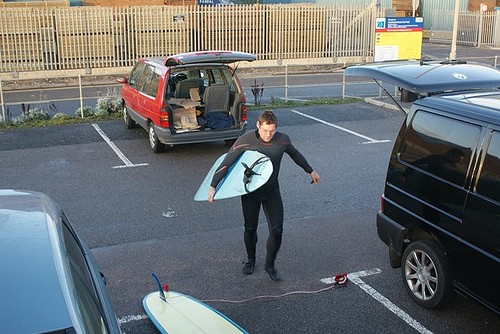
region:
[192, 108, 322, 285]
man walking with surfboard in arm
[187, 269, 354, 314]
red ankle band of surfboard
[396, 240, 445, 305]
silver rims on black van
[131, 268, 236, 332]
blue and white surfboard on pavement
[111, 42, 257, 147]
red van with hatch open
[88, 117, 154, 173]
white line on parking lot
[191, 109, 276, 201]
Surfboard under man's arm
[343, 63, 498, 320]
Black van with trunk open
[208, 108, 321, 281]
Man in black wetsuit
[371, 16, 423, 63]
Yellow, blue, red, and white sign on fence.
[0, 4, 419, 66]
White fence in front of brown pallets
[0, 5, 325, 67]
Five large brown boxes behind fence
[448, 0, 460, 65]
White pole in front of fence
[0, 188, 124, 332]
Blue car parked in parking lot.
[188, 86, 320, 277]
man in the parking lot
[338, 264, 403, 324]
white line on ground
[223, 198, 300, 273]
legs of the man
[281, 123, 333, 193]
arm of the man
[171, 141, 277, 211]
board in the man's hand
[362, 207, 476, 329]
wheel of the car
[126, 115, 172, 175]
back tire of car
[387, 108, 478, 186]
window on side of car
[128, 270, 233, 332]
board on the ground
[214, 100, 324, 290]
man in surfing suit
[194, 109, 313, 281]
man in suit carrying surfboard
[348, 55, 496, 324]
black minivan with open trunk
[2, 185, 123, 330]
blue top of car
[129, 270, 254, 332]
white and blue surfboard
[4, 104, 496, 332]
black asphalt parking lot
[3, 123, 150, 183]
painted parking spot on asphalt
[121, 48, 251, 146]
red minivan with open trunk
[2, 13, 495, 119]
fenced area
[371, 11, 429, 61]
business sign in lot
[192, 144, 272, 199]
Large long blue surfboard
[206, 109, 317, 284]
Tall white thin man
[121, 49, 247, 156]
Long red metal car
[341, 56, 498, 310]
Large black metal car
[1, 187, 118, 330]
Small blue metal car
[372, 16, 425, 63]
Large blue and yellow sign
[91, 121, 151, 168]
Long white parking line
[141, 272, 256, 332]
Long blue and white surfboard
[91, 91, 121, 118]
Small green and white bush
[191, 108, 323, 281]
man carrying a blue surfboard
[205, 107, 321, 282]
man walking in a parking lot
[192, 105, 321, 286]
man holding blue surfboard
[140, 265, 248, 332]
blue surfboard on parking lot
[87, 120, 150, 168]
white painted stripe on black concrete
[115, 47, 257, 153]
red van with open trunk door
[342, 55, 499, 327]
black cargo van with open trunk door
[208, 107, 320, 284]
man wearing a black wetsuit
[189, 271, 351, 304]
red handle and surfboard string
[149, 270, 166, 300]
blue fin of a surfboard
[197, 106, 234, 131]
blue blanket in back of trunk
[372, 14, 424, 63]
yellow sign with blue and red banners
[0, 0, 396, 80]
tan wooden privacy fence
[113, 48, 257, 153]
red van parked on the dark asphalt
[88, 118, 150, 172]
straight white line painted on asphalt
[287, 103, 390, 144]
straight white line painted on asphalt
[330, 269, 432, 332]
straight white line painted on asphalt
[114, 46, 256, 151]
red vehicle with open hatchback